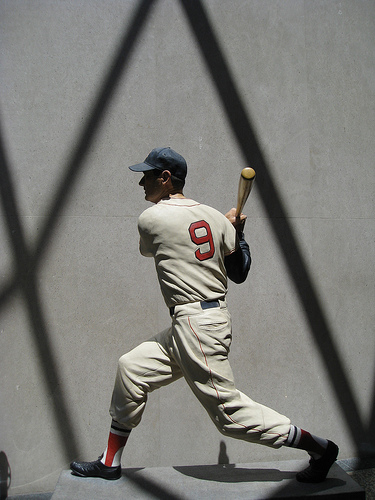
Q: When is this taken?
A: During a ball game.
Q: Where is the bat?
A: In the man's hands.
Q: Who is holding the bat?
A: The man.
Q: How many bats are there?
A: One.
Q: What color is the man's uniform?
A: White.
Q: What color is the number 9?
A: Red.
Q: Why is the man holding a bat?
A: He is playing baseball.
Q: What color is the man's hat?
A: Blue.